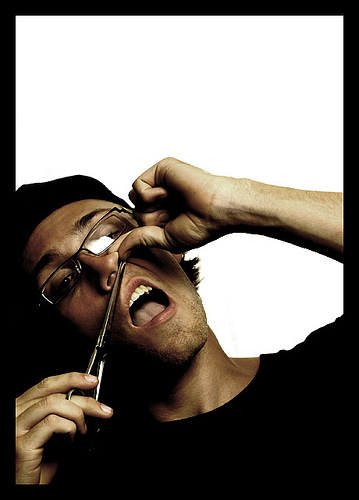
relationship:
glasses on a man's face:
[34, 200, 139, 309] [20, 198, 211, 375]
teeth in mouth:
[119, 282, 147, 303] [113, 278, 177, 328]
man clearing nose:
[16, 157, 344, 483] [79, 244, 127, 290]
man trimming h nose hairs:
[14, 173, 344, 483] [112, 252, 138, 275]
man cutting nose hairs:
[16, 157, 344, 483] [117, 255, 122, 269]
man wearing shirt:
[16, 157, 344, 483] [48, 315, 344, 490]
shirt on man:
[166, 348, 338, 498] [36, 162, 214, 356]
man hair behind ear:
[14, 173, 344, 483] [173, 248, 185, 264]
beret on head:
[14, 172, 79, 231] [17, 162, 82, 237]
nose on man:
[68, 249, 125, 288] [42, 174, 209, 389]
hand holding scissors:
[31, 375, 89, 465] [55, 260, 113, 410]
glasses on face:
[34, 204, 139, 310] [36, 202, 190, 377]